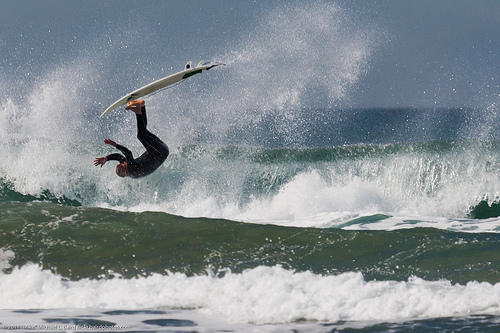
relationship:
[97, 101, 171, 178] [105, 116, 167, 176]
man wearing wetsuit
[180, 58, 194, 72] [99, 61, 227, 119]
fin on bottom of surfboard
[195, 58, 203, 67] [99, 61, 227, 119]
fin on bottom of surfboard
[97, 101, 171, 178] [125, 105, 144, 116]
man has foot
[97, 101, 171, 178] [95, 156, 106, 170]
man has hand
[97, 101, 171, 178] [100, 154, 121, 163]
man has arm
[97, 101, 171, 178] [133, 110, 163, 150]
man has leg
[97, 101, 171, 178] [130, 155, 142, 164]
man has chest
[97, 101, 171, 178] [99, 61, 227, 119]
man surfing surfboard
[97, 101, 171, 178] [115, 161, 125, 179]
man has head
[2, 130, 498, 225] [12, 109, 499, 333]
wave on top of water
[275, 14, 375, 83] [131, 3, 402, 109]
water droplets in air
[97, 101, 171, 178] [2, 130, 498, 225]
man surfing wave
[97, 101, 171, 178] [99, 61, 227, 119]
man under surfboard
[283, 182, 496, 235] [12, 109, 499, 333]
foam on top of water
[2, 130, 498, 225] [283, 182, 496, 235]
wave crashing into foam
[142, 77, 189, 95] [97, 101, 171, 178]
cord attached to man